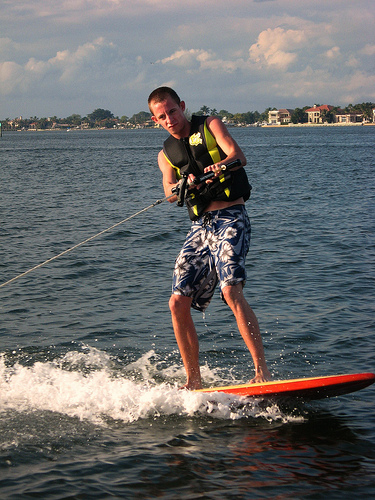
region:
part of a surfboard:
[180, 369, 371, 395]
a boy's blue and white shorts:
[167, 202, 248, 303]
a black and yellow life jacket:
[158, 111, 256, 216]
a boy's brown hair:
[146, 83, 178, 116]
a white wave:
[0, 345, 285, 424]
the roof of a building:
[306, 102, 326, 109]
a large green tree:
[84, 102, 114, 118]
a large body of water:
[0, 121, 371, 493]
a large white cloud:
[251, 24, 315, 65]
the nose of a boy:
[163, 113, 176, 124]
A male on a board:
[143, 85, 372, 391]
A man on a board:
[141, 86, 370, 400]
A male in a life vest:
[136, 87, 293, 384]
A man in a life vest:
[143, 84, 286, 385]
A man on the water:
[138, 83, 293, 478]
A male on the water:
[137, 81, 283, 438]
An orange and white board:
[152, 364, 371, 412]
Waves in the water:
[13, 355, 224, 427]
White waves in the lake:
[9, 357, 232, 425]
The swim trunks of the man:
[160, 214, 259, 298]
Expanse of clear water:
[0, 124, 373, 498]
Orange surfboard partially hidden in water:
[162, 367, 373, 405]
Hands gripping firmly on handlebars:
[164, 152, 247, 197]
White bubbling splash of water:
[0, 342, 294, 428]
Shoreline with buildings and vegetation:
[0, 98, 374, 131]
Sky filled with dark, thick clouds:
[1, 1, 374, 103]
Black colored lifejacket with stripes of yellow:
[158, 112, 259, 222]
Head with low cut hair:
[145, 83, 188, 137]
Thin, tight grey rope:
[0, 181, 179, 296]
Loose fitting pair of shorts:
[167, 200, 259, 315]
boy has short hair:
[134, 83, 202, 139]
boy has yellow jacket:
[143, 123, 244, 207]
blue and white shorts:
[196, 208, 252, 314]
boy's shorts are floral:
[165, 191, 263, 296]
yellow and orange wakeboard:
[175, 341, 371, 411]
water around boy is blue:
[287, 169, 365, 291]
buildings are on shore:
[265, 98, 374, 160]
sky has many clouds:
[37, 2, 285, 75]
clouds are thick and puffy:
[204, 12, 330, 88]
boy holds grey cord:
[3, 175, 176, 286]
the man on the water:
[146, 86, 273, 391]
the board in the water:
[165, 370, 374, 402]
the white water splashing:
[0, 336, 303, 420]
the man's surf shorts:
[170, 207, 251, 310]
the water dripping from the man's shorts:
[200, 311, 212, 332]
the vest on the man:
[160, 113, 252, 221]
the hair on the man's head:
[147, 86, 179, 114]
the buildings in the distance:
[0, 103, 374, 129]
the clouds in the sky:
[1, 1, 374, 118]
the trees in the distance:
[0, 102, 373, 130]